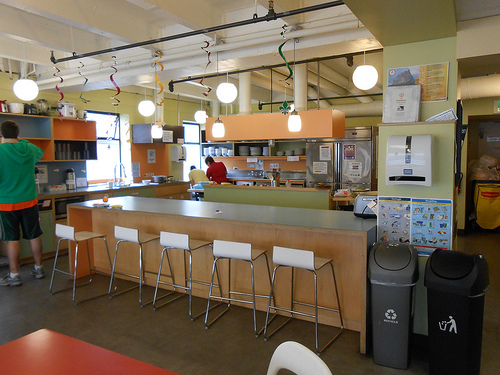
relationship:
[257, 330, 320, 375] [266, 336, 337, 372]
part of chair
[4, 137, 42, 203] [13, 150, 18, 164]
man in jacket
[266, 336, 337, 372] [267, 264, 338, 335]
chair with metal legs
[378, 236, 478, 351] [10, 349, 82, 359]
garbage cans by table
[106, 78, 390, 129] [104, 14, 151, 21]
lights hanging from ceiling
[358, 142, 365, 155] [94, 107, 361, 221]
refrigerator in kitchen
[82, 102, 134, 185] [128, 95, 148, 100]
window on wall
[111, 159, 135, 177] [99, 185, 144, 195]
faucet over sink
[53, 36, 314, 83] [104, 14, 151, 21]
ribbons hanging from ceiling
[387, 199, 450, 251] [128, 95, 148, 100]
pictures on wall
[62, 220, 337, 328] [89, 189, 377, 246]
chairs by counter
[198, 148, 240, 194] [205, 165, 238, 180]
woman wearing red shirt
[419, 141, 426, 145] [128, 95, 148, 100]
towel holder on wall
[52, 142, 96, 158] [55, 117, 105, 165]
bottles on shelf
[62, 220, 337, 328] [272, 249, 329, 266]
chairs have low backs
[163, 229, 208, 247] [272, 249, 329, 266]
chair has low backs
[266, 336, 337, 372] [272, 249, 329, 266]
chair has low backs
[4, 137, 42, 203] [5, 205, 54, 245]
man in shorts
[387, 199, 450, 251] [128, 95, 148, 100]
chart on wall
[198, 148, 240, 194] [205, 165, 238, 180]
woman in red shirt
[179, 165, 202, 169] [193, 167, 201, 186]
person in yellow shirt